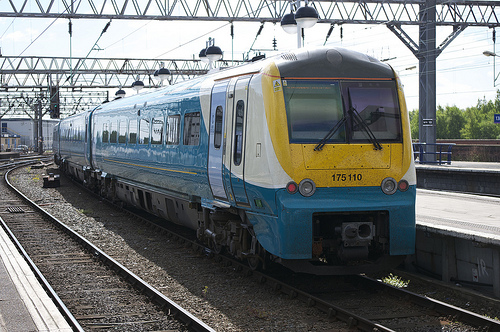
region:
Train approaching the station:
[60, 80, 457, 274]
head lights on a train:
[279, 162, 422, 205]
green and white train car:
[88, 100, 323, 257]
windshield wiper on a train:
[307, 80, 347, 155]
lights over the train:
[271, 5, 321, 30]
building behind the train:
[1, 108, 61, 153]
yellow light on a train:
[283, 178, 299, 198]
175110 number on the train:
[329, 170, 369, 184]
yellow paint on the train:
[260, 60, 420, 192]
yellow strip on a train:
[102, 152, 208, 188]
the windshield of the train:
[281, 79, 394, 139]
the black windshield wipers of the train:
[312, 90, 380, 154]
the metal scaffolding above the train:
[2, 3, 499, 125]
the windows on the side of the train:
[45, 110, 202, 151]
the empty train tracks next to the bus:
[3, 160, 214, 330]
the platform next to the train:
[419, 189, 499, 277]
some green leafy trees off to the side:
[408, 103, 498, 138]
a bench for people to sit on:
[408, 135, 455, 162]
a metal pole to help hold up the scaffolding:
[401, 31, 453, 163]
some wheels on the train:
[191, 218, 261, 273]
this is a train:
[120, 45, 412, 249]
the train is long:
[110, 34, 402, 239]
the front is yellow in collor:
[320, 143, 369, 174]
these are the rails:
[80, 260, 190, 327]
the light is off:
[300, 177, 317, 193]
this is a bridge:
[127, 0, 195, 16]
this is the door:
[205, 93, 257, 185]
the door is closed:
[209, 95, 245, 187]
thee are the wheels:
[208, 215, 255, 250]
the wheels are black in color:
[205, 213, 251, 254]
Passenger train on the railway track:
[58, 22, 425, 288]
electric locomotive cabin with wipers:
[244, 47, 432, 277]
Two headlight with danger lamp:
[281, 167, 418, 227]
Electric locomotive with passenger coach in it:
[93, 39, 425, 263]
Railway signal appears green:
[44, 75, 78, 128]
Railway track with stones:
[8, 191, 498, 329]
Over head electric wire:
[4, 5, 480, 169]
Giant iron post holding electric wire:
[4, 9, 488, 180]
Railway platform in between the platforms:
[416, 131, 496, 275]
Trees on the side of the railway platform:
[404, 90, 496, 152]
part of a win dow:
[285, 92, 315, 121]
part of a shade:
[185, 268, 216, 305]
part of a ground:
[158, 252, 213, 293]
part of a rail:
[125, 226, 165, 295]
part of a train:
[317, 207, 352, 246]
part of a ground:
[188, 272, 231, 307]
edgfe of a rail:
[145, 272, 184, 319]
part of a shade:
[163, 235, 189, 265]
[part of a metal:
[343, 207, 365, 242]